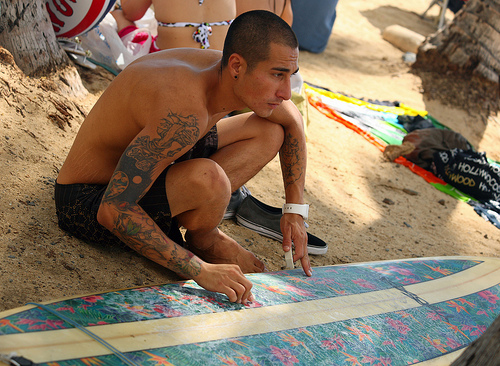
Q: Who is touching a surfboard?
A: A man.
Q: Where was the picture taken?
A: At the beach.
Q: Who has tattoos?
A: The man.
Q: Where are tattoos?
A: On a man's arm.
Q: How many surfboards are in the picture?
A: One.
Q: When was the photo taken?
A: Daytime.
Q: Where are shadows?
A: On the sand.